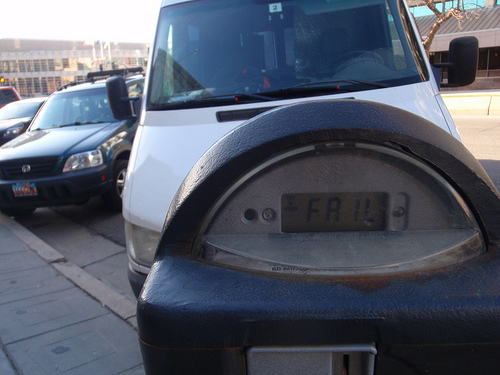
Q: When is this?
A: Daytime.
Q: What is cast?
A: Shadow.